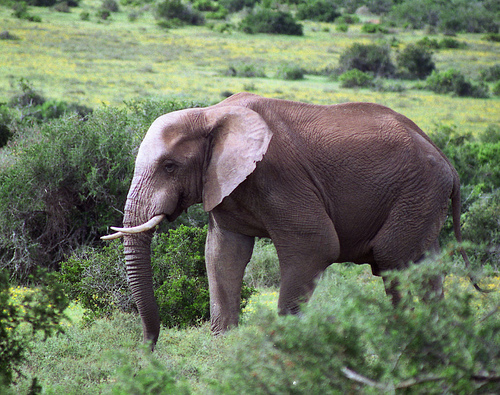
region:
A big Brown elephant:
[122, 123, 475, 311]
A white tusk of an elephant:
[113, 210, 178, 241]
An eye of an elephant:
[155, 157, 185, 182]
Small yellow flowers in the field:
[70, 25, 245, 82]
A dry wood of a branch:
[25, 181, 80, 256]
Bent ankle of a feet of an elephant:
[275, 205, 340, 296]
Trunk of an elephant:
[117, 231, 162, 356]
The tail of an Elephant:
[451, 175, 491, 315]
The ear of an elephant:
[198, 114, 272, 208]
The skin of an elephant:
[301, 123, 436, 245]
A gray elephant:
[86, 77, 485, 351]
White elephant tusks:
[92, 207, 192, 255]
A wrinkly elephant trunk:
[108, 240, 177, 359]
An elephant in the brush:
[43, 82, 492, 359]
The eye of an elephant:
[151, 142, 196, 187]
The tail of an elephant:
[437, 145, 493, 299]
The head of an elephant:
[120, 92, 241, 228]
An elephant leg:
[196, 220, 258, 342]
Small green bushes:
[326, 32, 481, 96]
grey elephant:
[86, 62, 469, 357]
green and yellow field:
[31, 11, 491, 122]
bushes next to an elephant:
[8, 100, 232, 292]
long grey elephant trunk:
[106, 192, 183, 358]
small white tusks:
[99, 207, 179, 242]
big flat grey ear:
[196, 102, 275, 211]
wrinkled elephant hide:
[289, 129, 444, 226]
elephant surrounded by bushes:
[42, 57, 476, 371]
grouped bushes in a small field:
[123, 0, 477, 82]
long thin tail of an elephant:
[438, 158, 493, 300]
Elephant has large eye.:
[153, 154, 183, 187]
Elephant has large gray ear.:
[208, 109, 277, 198]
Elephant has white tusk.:
[131, 206, 169, 241]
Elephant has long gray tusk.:
[110, 213, 155, 388]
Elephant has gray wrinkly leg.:
[263, 186, 335, 313]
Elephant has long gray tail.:
[449, 163, 489, 298]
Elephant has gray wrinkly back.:
[290, 88, 432, 163]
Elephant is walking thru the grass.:
[50, 115, 361, 337]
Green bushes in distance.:
[343, 67, 482, 104]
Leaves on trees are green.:
[24, 145, 69, 204]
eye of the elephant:
[159, 155, 181, 174]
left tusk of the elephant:
[111, 210, 162, 237]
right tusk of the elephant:
[96, 231, 124, 238]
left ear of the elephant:
[203, 116, 267, 213]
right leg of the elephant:
[207, 238, 252, 334]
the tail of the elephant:
[452, 180, 495, 303]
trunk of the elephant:
[125, 237, 151, 352]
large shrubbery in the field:
[9, 125, 121, 259]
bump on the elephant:
[425, 153, 438, 169]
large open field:
[37, 28, 224, 94]